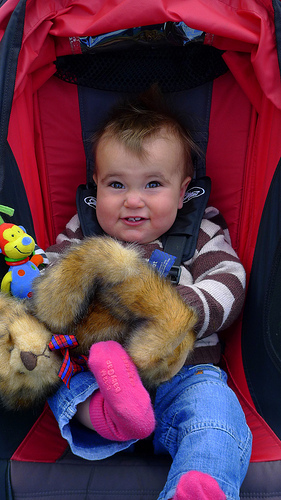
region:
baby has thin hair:
[96, 110, 195, 183]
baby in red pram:
[26, 22, 261, 311]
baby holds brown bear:
[8, 108, 211, 390]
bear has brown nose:
[22, 344, 45, 379]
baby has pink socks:
[92, 354, 154, 429]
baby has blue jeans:
[77, 360, 254, 498]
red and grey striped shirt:
[142, 221, 246, 317]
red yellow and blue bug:
[0, 212, 56, 304]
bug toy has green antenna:
[2, 204, 20, 224]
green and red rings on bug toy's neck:
[2, 254, 34, 265]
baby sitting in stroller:
[23, 69, 274, 351]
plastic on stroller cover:
[71, 19, 206, 54]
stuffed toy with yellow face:
[2, 221, 38, 298]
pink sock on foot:
[89, 340, 153, 441]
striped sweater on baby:
[39, 208, 245, 358]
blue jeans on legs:
[53, 359, 252, 491]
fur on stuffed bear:
[2, 240, 184, 400]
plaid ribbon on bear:
[51, 330, 84, 382]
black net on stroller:
[53, 48, 225, 90]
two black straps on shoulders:
[76, 177, 209, 256]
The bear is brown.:
[0, 236, 189, 414]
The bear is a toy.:
[0, 239, 189, 408]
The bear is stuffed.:
[1, 238, 191, 405]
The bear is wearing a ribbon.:
[45, 329, 92, 387]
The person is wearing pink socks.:
[84, 337, 155, 441]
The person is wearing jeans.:
[46, 362, 253, 499]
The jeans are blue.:
[44, 362, 251, 498]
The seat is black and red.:
[0, 0, 280, 499]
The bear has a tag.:
[146, 248, 175, 281]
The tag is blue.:
[145, 248, 175, 278]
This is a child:
[44, 113, 261, 494]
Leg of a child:
[45, 327, 163, 475]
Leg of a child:
[153, 359, 254, 497]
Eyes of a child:
[99, 167, 174, 197]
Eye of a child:
[104, 174, 131, 196]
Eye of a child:
[143, 169, 161, 193]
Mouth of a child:
[117, 209, 164, 232]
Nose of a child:
[125, 191, 146, 213]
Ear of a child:
[178, 171, 190, 223]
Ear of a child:
[85, 168, 101, 198]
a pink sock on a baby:
[83, 337, 155, 441]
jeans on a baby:
[45, 363, 258, 498]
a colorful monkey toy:
[0, 204, 44, 308]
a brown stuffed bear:
[0, 235, 195, 409]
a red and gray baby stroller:
[0, 1, 279, 497]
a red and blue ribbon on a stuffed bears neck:
[47, 332, 92, 388]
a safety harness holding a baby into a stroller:
[72, 172, 215, 289]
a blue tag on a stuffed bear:
[147, 248, 176, 278]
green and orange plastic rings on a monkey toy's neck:
[3, 254, 29, 265]